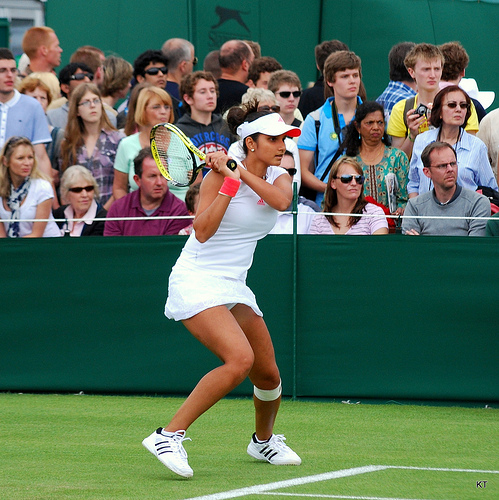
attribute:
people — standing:
[9, 16, 492, 219]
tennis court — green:
[7, 392, 498, 495]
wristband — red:
[211, 173, 253, 212]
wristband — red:
[215, 174, 243, 200]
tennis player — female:
[137, 97, 309, 476]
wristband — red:
[191, 158, 272, 228]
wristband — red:
[209, 169, 261, 215]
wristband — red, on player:
[216, 173, 245, 201]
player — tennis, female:
[140, 98, 304, 480]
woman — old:
[39, 158, 103, 249]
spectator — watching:
[306, 155, 388, 233]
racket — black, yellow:
[142, 117, 207, 185]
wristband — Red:
[218, 173, 241, 202]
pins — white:
[139, 420, 302, 480]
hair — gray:
[57, 158, 99, 201]